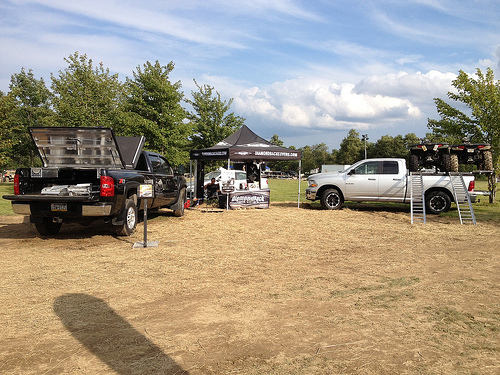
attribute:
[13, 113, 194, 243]
truck — leafy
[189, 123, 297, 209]
tent — black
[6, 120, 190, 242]
truck — black, pick up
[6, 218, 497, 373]
dirt — brown 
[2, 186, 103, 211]
tailgate — down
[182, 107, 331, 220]
tent — black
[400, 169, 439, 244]
ramps — metal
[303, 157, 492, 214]
truck — silver, four wheeled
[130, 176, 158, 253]
sign — black 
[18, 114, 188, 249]
truck — black, parked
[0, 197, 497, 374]
dirt — brown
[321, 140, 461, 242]
truck — pickup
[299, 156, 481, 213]
silver pickup — truck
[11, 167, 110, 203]
bed — open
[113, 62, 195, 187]
tree — small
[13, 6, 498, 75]
sky — pale blue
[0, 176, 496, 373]
ground — dirt 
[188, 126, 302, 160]
tent — black